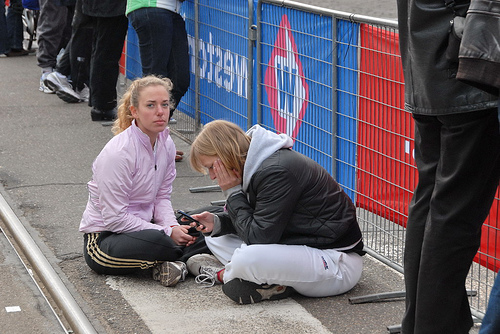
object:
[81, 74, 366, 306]
woman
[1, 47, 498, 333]
sidewalk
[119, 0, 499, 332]
fence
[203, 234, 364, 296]
pants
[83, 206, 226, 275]
pants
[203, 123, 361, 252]
jacket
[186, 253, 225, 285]
shoe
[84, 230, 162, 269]
stripes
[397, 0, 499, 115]
jacket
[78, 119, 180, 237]
jacket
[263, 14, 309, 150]
logo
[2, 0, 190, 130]
legs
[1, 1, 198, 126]
people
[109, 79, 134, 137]
pony tail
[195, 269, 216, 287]
laces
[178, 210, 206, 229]
phone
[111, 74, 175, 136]
hair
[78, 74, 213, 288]
lady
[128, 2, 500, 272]
banner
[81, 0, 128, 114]
pants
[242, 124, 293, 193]
hood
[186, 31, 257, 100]
word